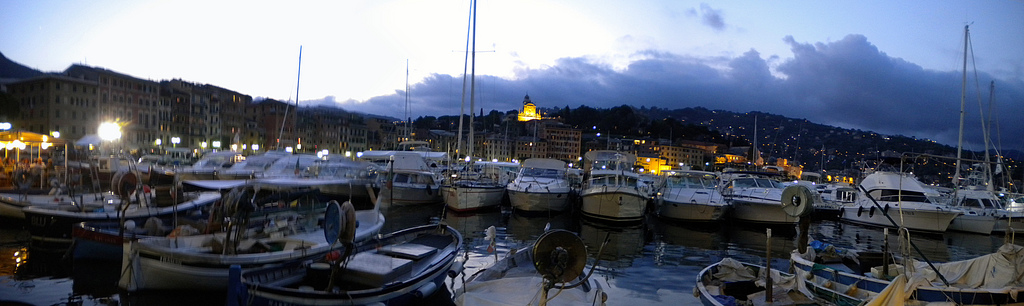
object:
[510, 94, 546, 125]
light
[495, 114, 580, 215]
boat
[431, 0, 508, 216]
boat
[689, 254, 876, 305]
boat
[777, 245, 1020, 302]
boat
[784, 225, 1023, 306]
boat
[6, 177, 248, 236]
boat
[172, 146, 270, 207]
boat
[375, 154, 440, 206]
boat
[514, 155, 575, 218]
boat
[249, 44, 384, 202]
boat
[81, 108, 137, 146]
light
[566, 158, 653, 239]
boat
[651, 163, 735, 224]
boat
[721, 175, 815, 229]
boat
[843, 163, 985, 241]
boat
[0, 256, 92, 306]
water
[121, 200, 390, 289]
boat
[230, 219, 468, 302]
boat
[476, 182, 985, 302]
water